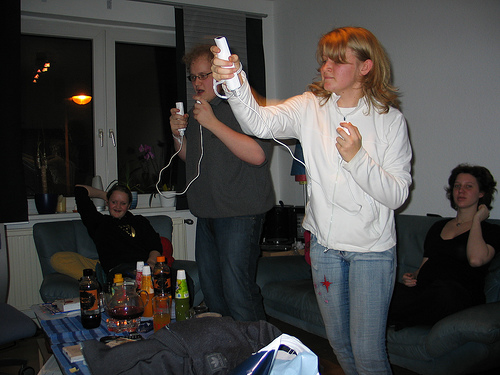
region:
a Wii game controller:
[211, 35, 238, 89]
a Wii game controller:
[174, 99, 184, 136]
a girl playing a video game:
[213, 26, 413, 373]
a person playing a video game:
[156, 46, 271, 319]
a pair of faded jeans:
[307, 234, 396, 373]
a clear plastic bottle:
[79, 269, 101, 330]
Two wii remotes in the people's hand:
[121, 25, 334, 197]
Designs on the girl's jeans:
[303, 268, 342, 308]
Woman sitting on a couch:
[377, 158, 497, 336]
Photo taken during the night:
[15, 30, 225, 198]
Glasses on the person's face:
[185, 69, 222, 83]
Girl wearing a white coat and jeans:
[267, 20, 410, 367]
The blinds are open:
[8, 0, 294, 205]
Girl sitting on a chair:
[69, 176, 194, 292]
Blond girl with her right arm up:
[203, 0, 413, 348]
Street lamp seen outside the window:
[58, 81, 100, 190]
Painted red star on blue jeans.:
[294, 229, 364, 326]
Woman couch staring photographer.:
[414, 164, 492, 316]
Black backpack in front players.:
[79, 322, 285, 374]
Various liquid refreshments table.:
[72, 254, 194, 335]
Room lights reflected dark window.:
[25, 47, 115, 117]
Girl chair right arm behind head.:
[74, 179, 156, 261]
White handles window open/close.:
[87, 112, 125, 156]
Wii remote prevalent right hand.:
[200, 26, 266, 131]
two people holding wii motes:
[154, 25, 414, 374]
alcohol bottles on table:
[79, 252, 195, 338]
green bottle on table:
[170, 268, 191, 321]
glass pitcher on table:
[102, 275, 152, 321]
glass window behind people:
[16, 30, 181, 197]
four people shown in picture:
[66, 25, 498, 335]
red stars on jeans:
[316, 273, 333, 308]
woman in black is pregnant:
[390, 161, 499, 329]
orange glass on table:
[149, 294, 168, 336]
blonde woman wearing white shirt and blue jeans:
[211, 26, 410, 373]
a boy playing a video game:
[168, 47, 275, 319]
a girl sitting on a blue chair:
[73, 184, 163, 272]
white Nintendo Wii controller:
[212, 34, 242, 91]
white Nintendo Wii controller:
[174, 99, 188, 136]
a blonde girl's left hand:
[333, 122, 364, 162]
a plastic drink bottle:
[76, 267, 103, 329]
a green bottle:
[169, 269, 190, 320]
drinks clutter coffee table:
[71, 254, 193, 341]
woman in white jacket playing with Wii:
[212, 28, 402, 268]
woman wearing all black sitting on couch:
[381, 160, 498, 367]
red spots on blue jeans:
[312, 269, 333, 301]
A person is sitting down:
[411, 151, 481, 308]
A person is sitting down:
[69, 162, 177, 292]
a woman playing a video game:
[211, 27, 414, 373]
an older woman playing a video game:
[169, 44, 270, 317]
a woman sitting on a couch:
[385, 165, 496, 327]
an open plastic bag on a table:
[232, 336, 322, 373]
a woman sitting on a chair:
[73, 182, 161, 289]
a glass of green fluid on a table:
[175, 271, 190, 322]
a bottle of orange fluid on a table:
[139, 267, 151, 316]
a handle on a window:
[97, 130, 104, 147]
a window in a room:
[1, 17, 108, 217]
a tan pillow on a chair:
[49, 251, 98, 277]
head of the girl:
[282, 16, 414, 118]